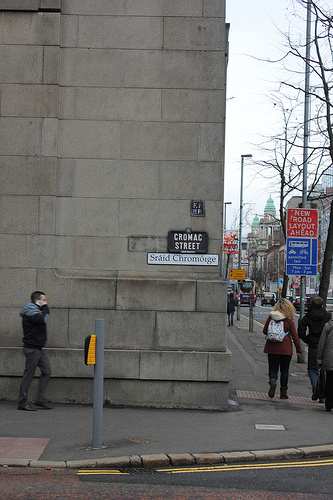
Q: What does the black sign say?
A: Cromac street.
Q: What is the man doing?
A: Talking on phone.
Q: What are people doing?
A: Walking.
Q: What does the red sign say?
A: New road layout ahead.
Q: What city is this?
A: Montreal.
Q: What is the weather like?
A: Cloudy.